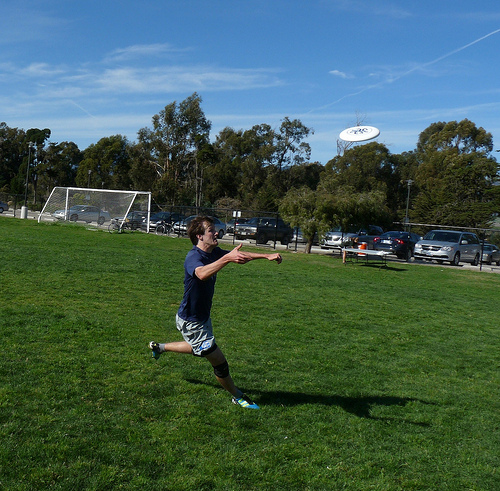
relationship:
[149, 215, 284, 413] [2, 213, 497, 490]
man on field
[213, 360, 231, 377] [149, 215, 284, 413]
brace on man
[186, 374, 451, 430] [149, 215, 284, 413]
shadow of man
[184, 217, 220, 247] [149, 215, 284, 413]
head of man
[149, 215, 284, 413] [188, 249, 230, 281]
man has an arm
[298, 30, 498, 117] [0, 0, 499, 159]
vapor trail in sky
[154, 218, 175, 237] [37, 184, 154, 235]
bike by goal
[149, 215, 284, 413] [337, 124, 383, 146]
man catching frisbee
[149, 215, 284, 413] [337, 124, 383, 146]
man throwing frisbee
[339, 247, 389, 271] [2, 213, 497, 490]
table in field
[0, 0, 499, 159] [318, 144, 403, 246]
sky above tree